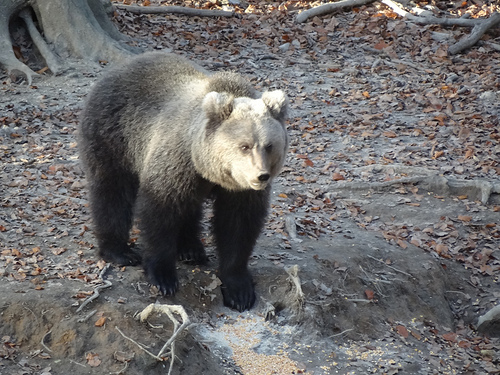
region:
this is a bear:
[95, 62, 275, 302]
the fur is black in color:
[145, 205, 160, 240]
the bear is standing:
[85, 50, 290, 310]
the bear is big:
[91, 70, 266, 310]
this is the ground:
[328, 87, 403, 153]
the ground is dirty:
[363, 73, 493, 141]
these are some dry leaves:
[437, 80, 495, 164]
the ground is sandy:
[19, 294, 53, 324]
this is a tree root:
[6, 0, 120, 60]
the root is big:
[7, 2, 103, 60]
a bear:
[43, 19, 389, 342]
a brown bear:
[55, 45, 421, 350]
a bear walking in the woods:
[39, 14, 482, 326]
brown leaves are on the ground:
[31, 11, 498, 368]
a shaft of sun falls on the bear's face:
[50, 14, 498, 332]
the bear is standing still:
[73, 41, 360, 340]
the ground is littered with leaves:
[13, 4, 494, 374]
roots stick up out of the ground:
[68, 251, 400, 373]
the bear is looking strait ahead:
[67, 38, 448, 371]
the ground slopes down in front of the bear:
[37, 89, 499, 370]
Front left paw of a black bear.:
[217, 270, 257, 312]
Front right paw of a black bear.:
[139, 251, 181, 300]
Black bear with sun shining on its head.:
[78, 48, 290, 310]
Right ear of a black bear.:
[200, 87, 234, 121]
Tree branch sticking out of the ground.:
[136, 297, 188, 374]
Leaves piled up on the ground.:
[368, 12, 393, 49]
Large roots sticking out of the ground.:
[357, 160, 499, 205]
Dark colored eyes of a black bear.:
[238, 143, 275, 153]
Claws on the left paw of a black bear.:
[228, 301, 247, 313]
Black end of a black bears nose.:
[255, 172, 270, 180]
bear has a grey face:
[201, 125, 284, 192]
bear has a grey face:
[183, 87, 325, 199]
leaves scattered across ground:
[290, 160, 494, 337]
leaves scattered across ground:
[313, 195, 470, 242]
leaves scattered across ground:
[21, 222, 58, 258]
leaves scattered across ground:
[340, 209, 452, 282]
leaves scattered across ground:
[44, 165, 125, 285]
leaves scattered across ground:
[300, 145, 465, 243]